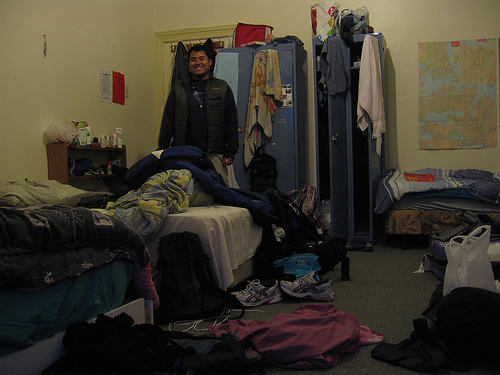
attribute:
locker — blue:
[312, 33, 386, 252]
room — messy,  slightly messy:
[2, 0, 499, 374]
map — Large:
[412, 36, 498, 148]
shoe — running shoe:
[280, 270, 341, 302]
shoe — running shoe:
[226, 274, 290, 304]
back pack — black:
[149, 227, 257, 328]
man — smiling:
[167, 37, 236, 164]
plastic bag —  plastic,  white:
[455, 221, 492, 264]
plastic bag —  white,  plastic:
[442, 219, 497, 294]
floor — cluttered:
[224, 244, 426, 373]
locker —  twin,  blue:
[256, 37, 306, 204]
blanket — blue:
[0, 218, 132, 352]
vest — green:
[172, 77, 254, 171]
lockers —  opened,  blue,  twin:
[280, 32, 398, 259]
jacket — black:
[158, 75, 241, 157]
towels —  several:
[239, 40, 389, 175]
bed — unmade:
[334, 153, 496, 243]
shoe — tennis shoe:
[225, 278, 285, 304]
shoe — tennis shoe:
[279, 268, 336, 298]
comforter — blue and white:
[375, 165, 496, 214]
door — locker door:
[360, 34, 385, 252]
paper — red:
[113, 74, 126, 103]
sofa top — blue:
[4, 246, 136, 351]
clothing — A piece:
[243, 48, 285, 165]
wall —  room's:
[378, 6, 416, 169]